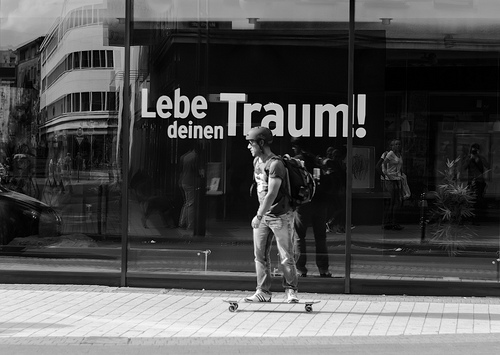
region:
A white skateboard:
[218, 292, 320, 316]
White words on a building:
[134, 80, 371, 145]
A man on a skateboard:
[224, 126, 321, 313]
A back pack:
[285, 150, 319, 206]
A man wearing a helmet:
[243, 125, 280, 157]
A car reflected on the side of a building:
[0, 182, 67, 242]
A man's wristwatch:
[253, 211, 262, 222]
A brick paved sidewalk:
[7, 285, 499, 351]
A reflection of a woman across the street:
[378, 136, 413, 232]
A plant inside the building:
[422, 170, 472, 259]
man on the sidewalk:
[190, 86, 372, 310]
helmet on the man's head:
[236, 110, 282, 151]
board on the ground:
[206, 275, 329, 333]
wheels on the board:
[223, 294, 245, 319]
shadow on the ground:
[354, 280, 493, 343]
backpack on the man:
[282, 145, 323, 213]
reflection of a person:
[363, 125, 433, 218]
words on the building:
[103, 78, 390, 171]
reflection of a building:
[27, 80, 129, 162]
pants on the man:
[226, 210, 314, 312]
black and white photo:
[3, 20, 484, 340]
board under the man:
[219, 291, 321, 322]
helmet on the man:
[229, 109, 277, 166]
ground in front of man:
[120, 287, 202, 337]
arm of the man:
[235, 173, 287, 235]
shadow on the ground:
[1, 301, 86, 351]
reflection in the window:
[148, 157, 211, 227]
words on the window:
[133, 75, 393, 159]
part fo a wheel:
[300, 299, 313, 315]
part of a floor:
[213, 310, 233, 327]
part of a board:
[268, 265, 299, 346]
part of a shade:
[230, 313, 255, 348]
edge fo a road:
[368, 283, 389, 317]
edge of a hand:
[256, 319, 282, 348]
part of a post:
[328, 191, 363, 266]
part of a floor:
[225, 303, 248, 336]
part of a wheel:
[219, 289, 239, 319]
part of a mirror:
[298, 199, 338, 251]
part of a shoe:
[242, 274, 267, 310]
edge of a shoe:
[286, 290, 300, 305]